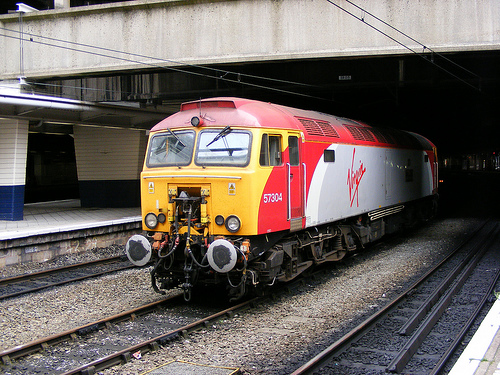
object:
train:
[125, 97, 441, 305]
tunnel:
[28, 50, 500, 219]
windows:
[150, 133, 192, 167]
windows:
[287, 136, 300, 165]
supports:
[1, 117, 33, 218]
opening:
[178, 186, 202, 224]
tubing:
[186, 203, 209, 267]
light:
[191, 117, 201, 126]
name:
[347, 146, 368, 209]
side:
[257, 99, 440, 235]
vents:
[297, 118, 324, 136]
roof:
[153, 95, 436, 146]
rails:
[1, 301, 209, 375]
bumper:
[124, 233, 162, 266]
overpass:
[2, 1, 498, 78]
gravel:
[23, 218, 470, 375]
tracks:
[1, 222, 500, 375]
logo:
[344, 146, 369, 206]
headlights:
[145, 213, 158, 229]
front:
[142, 108, 257, 292]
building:
[0, 73, 146, 216]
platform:
[1, 199, 144, 243]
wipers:
[206, 126, 230, 147]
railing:
[288, 160, 309, 222]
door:
[288, 132, 302, 218]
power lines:
[1, 1, 482, 99]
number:
[263, 193, 269, 203]